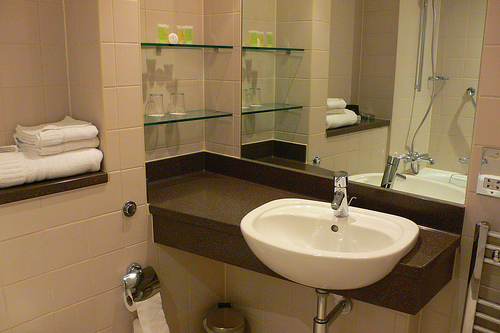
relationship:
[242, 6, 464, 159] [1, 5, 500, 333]
mirror inside of bathroom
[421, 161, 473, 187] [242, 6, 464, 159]
bathtub reflection in mirror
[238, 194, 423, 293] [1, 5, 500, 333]
sink inside of bathroom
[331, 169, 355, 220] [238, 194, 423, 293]
faucet in sink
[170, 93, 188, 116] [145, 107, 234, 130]
glass on top of shelf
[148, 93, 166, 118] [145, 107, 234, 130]
glass on top of shelf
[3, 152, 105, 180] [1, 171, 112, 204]
towel on top of shelf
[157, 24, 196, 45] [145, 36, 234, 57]
toiletries on top of shelf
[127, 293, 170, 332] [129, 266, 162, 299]
toilet paper on roll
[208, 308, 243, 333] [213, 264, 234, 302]
garbage can sitting in corner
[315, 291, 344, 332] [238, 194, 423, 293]
pipes under sink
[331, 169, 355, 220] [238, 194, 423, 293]
faucet on top of sink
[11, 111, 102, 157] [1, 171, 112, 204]
towel on top of shelf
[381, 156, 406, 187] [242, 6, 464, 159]
reflection in mirror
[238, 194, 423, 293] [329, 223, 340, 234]
sink has drain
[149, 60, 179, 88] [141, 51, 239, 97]
shadow on wall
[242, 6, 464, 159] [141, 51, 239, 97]
mirror hanging on wall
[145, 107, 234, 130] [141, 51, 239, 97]
shelf hanging on wall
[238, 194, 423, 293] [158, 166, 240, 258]
sink on top of counter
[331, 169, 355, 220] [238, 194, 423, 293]
faucet over sink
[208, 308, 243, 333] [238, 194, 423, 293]
garbage can under sink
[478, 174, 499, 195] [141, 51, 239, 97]
plug in on wall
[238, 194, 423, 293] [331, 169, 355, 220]
sink has faucet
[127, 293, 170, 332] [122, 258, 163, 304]
toilet paper hanging on toilet paper holder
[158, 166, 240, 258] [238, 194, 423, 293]
counter with sink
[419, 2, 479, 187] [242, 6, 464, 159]
shower in reflection of mirror